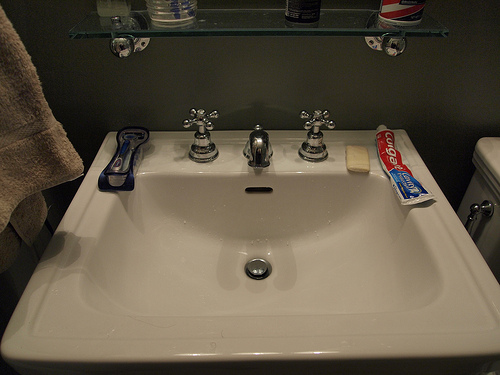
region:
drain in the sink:
[204, 230, 298, 290]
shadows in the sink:
[201, 231, 307, 303]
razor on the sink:
[101, 120, 161, 187]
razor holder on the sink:
[84, 121, 157, 201]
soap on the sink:
[331, 139, 374, 179]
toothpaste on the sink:
[370, 115, 440, 237]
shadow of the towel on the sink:
[21, 226, 99, 284]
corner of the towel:
[1, 61, 98, 205]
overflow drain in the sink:
[236, 179, 281, 199]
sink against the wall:
[25, 85, 487, 364]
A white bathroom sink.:
[2, 128, 499, 368]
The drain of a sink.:
[243, 257, 274, 281]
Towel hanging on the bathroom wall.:
[5, 93, 86, 253]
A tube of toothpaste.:
[373, 124, 437, 209]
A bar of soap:
[343, 141, 372, 174]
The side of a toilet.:
[463, 136, 499, 243]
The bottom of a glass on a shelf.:
[143, 0, 202, 30]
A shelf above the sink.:
[79, 14, 455, 39]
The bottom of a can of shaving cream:
[375, 0, 429, 26]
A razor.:
[97, 120, 154, 193]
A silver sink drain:
[241, 255, 273, 278]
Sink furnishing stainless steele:
[180, 102, 337, 174]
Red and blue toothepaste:
[372, 118, 430, 208]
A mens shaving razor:
[105, 120, 146, 193]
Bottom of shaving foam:
[378, 1, 431, 30]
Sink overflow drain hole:
[241, 182, 275, 197]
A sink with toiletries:
[4, 118, 499, 365]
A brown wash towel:
[0, 18, 97, 262]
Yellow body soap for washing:
[345, 143, 370, 172]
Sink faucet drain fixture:
[240, 122, 275, 170]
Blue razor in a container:
[95, 126, 149, 193]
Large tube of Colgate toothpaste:
[374, 121, 434, 206]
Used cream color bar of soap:
[342, 143, 369, 172]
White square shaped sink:
[0, 108, 498, 374]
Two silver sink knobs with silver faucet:
[177, 105, 335, 170]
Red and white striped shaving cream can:
[376, 0, 426, 28]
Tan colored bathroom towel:
[0, 0, 85, 280]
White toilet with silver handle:
[451, 135, 498, 285]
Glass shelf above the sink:
[66, 9, 452, 56]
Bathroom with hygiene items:
[0, 0, 497, 373]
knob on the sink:
[181, 105, 221, 159]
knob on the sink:
[293, 108, 332, 165]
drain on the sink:
[243, 260, 273, 285]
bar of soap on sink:
[344, 142, 368, 175]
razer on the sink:
[108, 128, 145, 182]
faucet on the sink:
[240, 126, 271, 175]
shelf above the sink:
[48, 13, 423, 40]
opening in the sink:
[238, 185, 275, 201]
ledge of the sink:
[445, 225, 481, 254]